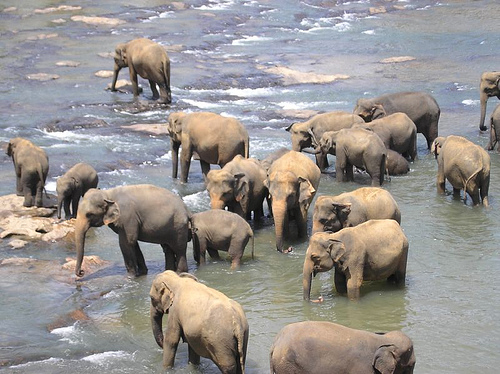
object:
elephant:
[109, 38, 172, 106]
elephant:
[54, 161, 99, 220]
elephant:
[72, 183, 199, 279]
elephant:
[150, 269, 253, 374]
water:
[0, 0, 496, 373]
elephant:
[186, 209, 255, 271]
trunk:
[72, 215, 89, 278]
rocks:
[26, 71, 58, 85]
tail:
[249, 230, 257, 263]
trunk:
[302, 255, 324, 302]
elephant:
[382, 149, 414, 177]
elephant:
[263, 149, 322, 253]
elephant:
[302, 127, 392, 187]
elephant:
[298, 218, 410, 301]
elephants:
[5, 136, 50, 207]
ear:
[328, 238, 345, 262]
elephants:
[53, 163, 101, 218]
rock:
[1, 194, 78, 253]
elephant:
[429, 133, 492, 207]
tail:
[462, 162, 484, 208]